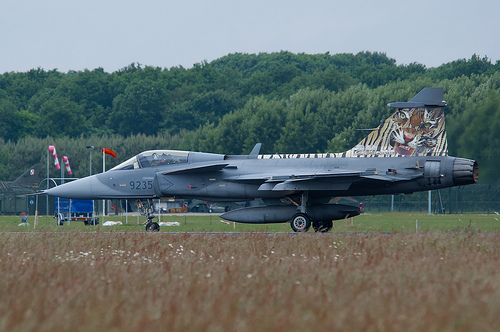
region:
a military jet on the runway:
[41, 86, 478, 231]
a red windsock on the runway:
[100, 145, 117, 169]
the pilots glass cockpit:
[111, 149, 188, 169]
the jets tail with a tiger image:
[350, 87, 449, 155]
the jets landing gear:
[290, 190, 310, 233]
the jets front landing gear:
[136, 196, 161, 232]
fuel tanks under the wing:
[220, 199, 362, 222]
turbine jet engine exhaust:
[422, 154, 478, 188]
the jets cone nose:
[40, 172, 153, 197]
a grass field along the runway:
[0, 230, 499, 330]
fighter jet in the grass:
[28, 85, 476, 259]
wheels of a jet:
[283, 200, 314, 240]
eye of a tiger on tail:
[421, 115, 438, 138]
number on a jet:
[121, 171, 156, 191]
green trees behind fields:
[31, 67, 346, 137]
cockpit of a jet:
[111, 140, 191, 165]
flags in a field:
[40, 140, 125, 170]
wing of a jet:
[165, 160, 235, 175]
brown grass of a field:
[212, 265, 440, 323]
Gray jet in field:
[43, 88, 478, 240]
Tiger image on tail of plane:
[390, 105, 444, 154]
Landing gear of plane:
[290, 210, 332, 235]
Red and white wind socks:
[47, 142, 71, 172]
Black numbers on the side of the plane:
[130, 178, 154, 188]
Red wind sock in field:
[105, 146, 120, 159]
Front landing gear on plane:
[146, 220, 163, 230]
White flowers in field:
[34, 231, 354, 263]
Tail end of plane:
[455, 156, 480, 181]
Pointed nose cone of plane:
[42, 175, 99, 197]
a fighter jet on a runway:
[13, 68, 498, 253]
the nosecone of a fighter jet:
[38, 175, 71, 206]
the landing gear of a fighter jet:
[131, 197, 175, 232]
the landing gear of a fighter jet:
[281, 198, 316, 235]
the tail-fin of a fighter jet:
[365, 74, 474, 150]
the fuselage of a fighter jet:
[113, 154, 408, 199]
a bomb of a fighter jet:
[217, 198, 364, 227]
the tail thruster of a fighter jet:
[446, 148, 483, 194]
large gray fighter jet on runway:
[41, 92, 491, 238]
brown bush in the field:
[154, 265, 310, 309]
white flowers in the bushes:
[63, 242, 177, 269]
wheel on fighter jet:
[280, 212, 315, 239]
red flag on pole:
[95, 143, 122, 163]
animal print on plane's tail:
[337, 109, 469, 161]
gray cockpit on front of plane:
[120, 130, 202, 172]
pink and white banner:
[18, 137, 75, 173]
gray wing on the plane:
[216, 152, 369, 189]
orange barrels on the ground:
[161, 199, 198, 218]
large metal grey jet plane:
[40, 87, 480, 235]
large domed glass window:
[109, 147, 198, 172]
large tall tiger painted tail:
[350, 86, 452, 155]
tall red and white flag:
[45, 141, 63, 211]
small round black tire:
[289, 211, 309, 231]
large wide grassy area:
[0, 211, 499, 228]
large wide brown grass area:
[0, 227, 497, 329]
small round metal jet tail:
[451, 156, 483, 186]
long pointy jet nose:
[40, 173, 122, 198]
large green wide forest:
[1, 49, 498, 211]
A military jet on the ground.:
[38, 84, 490, 236]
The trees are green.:
[86, 68, 489, 142]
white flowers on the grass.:
[65, 237, 204, 262]